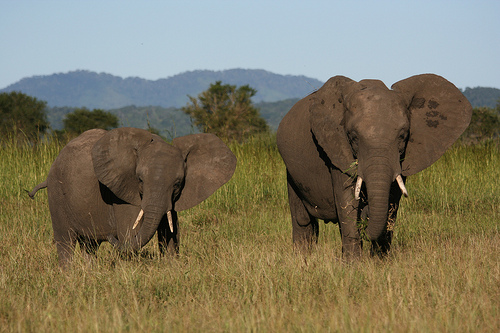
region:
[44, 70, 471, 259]
A parent and child elephant pair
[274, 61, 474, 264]
The larger elephant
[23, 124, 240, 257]
The small cute elephant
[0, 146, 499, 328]
High grassy area around elephants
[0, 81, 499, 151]
Tall green trees behind elephants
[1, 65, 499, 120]
Mountains in the background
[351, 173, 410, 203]
Two white elephant tusks on large elephant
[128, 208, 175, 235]
Two white tusk on small elephat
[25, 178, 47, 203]
Cute tail of the small elephant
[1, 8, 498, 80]
Clear sky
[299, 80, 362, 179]
the elephant has wide ears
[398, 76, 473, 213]
the elephant has wide ears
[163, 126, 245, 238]
the elephant has wide ears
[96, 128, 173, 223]
the elephant has wide ears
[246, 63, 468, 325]
the elephant is brown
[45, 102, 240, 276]
the elephant is brown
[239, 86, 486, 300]
the elephant is brown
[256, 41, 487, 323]
the elephant is brown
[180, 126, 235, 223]
ear on an elephant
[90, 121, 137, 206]
ear on an elephant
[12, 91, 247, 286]
brown elephant in grass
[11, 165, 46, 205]
tail on an elephant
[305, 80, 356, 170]
ear of an elephant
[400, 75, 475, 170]
ear of an elephant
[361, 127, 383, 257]
trunk on an elephant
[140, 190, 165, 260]
trunk on an elephant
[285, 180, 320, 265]
leg of an elephant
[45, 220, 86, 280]
leg of an elephant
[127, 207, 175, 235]
two white elephant tusks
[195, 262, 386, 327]
green and brown grasslands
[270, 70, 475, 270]
large elephant in grasslands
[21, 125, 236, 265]
smaller elephant in grasslands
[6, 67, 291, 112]
mountain terrain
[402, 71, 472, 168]
light and dark brown elephant ear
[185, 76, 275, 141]
green tree in background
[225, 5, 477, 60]
blue cloudless skies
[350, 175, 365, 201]
curved white elephant tusk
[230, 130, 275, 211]
tall green and brown grass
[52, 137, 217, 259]
Elephant in the photo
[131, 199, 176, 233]
Elephant tusks in the picture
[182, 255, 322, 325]
Grass in the field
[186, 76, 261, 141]
A tree in the photo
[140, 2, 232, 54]
A clear sky in the photo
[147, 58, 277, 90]
A hill in the photo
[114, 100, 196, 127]
Trees in the forest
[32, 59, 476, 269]
Elephants in the photo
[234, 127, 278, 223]
Grass in the photo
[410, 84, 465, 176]
Big ears of an elephant